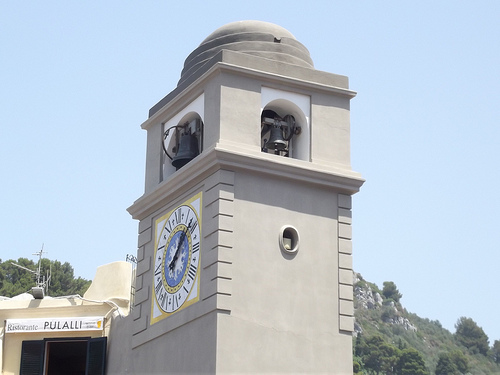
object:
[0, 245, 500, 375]
background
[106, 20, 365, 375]
tower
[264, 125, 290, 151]
bell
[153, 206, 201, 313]
clock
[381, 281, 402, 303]
tree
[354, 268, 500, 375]
hill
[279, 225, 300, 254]
hole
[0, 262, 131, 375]
building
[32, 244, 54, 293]
antenna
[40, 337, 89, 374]
doorway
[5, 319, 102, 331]
sign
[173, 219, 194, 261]
hand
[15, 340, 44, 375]
window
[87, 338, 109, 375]
window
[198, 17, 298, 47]
dome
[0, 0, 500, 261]
sky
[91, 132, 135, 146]
clouds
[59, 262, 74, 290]
tree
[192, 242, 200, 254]
roman numerals